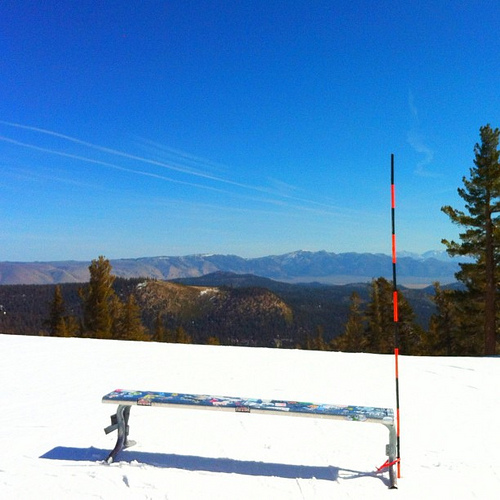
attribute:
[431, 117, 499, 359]
pine tree — green, tall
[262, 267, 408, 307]
trees — green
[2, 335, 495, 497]
snow — white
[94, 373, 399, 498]
bench — metal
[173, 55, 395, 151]
sky — bright, blue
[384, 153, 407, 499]
pole — black, red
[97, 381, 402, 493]
bench — multi colored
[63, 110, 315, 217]
lines — white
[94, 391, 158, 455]
legs — metal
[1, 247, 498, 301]
mountain range — distant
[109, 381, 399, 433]
seat — colorful